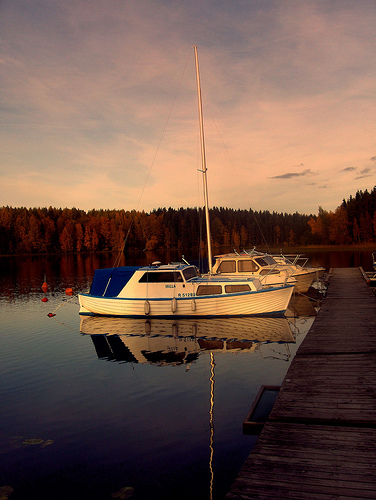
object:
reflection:
[80, 315, 297, 367]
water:
[2, 245, 331, 499]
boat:
[77, 259, 295, 318]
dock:
[225, 267, 375, 498]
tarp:
[88, 265, 147, 299]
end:
[74, 261, 141, 325]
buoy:
[38, 295, 51, 304]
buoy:
[45, 310, 55, 318]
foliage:
[2, 206, 374, 246]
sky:
[1, 1, 375, 215]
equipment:
[258, 263, 293, 284]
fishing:
[111, 475, 147, 498]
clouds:
[266, 150, 375, 193]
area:
[3, 3, 373, 493]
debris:
[233, 379, 282, 434]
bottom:
[215, 382, 321, 447]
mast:
[192, 41, 214, 277]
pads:
[10, 433, 55, 453]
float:
[187, 299, 199, 313]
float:
[169, 296, 181, 315]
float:
[141, 298, 151, 316]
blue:
[78, 290, 295, 301]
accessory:
[151, 260, 182, 269]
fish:
[124, 417, 155, 432]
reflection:
[200, 334, 222, 499]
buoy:
[41, 278, 50, 292]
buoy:
[64, 285, 72, 295]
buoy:
[47, 309, 54, 323]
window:
[224, 284, 251, 293]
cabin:
[136, 262, 259, 293]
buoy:
[47, 311, 53, 318]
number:
[177, 292, 196, 297]